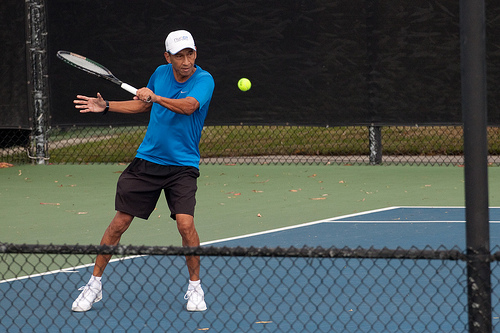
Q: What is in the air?
A: The tennis ball.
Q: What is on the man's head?
A: A white hat.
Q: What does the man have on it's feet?
A: Tennis shoes.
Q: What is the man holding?
A: A tennis racket.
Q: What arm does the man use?
A: His left.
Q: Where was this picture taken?
A: A tennis court.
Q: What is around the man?
A: A fence.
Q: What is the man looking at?
A: The ball.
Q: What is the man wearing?
A: Shirt and shorts.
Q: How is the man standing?
A: He is standing legs apart.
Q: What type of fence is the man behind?
A: Chain link.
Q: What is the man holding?
A: A tennis racket.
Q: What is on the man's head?
A: A hat.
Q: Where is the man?
A: On a tennis court.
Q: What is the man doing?
A: Playing tennis.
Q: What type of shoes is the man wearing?
A: Tennis shoes.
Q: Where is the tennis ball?
A: In the air.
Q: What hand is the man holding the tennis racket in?
A: Left.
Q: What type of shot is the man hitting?
A: A backhand.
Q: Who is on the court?
A: A man.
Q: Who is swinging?
A: The man.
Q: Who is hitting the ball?
A: The man.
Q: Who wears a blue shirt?
A: The man.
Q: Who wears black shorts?
A: The man.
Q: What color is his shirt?
A: Blue.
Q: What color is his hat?
A: White.